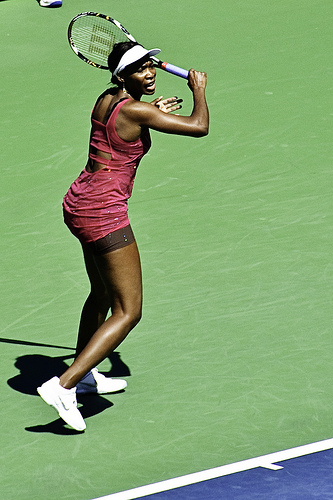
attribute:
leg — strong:
[58, 242, 143, 389]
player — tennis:
[35, 40, 210, 433]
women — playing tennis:
[35, 7, 223, 431]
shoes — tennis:
[22, 340, 146, 445]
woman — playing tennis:
[60, 40, 209, 432]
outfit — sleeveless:
[58, 76, 152, 257]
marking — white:
[97, 431, 330, 499]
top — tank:
[57, 84, 154, 242]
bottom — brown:
[80, 223, 135, 256]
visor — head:
[110, 44, 162, 79]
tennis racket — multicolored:
[67, 12, 207, 88]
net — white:
[67, 16, 122, 70]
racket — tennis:
[66, 10, 190, 78]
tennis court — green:
[2, 1, 329, 498]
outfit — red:
[58, 89, 162, 265]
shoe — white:
[30, 342, 132, 456]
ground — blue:
[110, 434, 332, 496]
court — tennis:
[0, 1, 320, 498]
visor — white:
[108, 36, 163, 80]